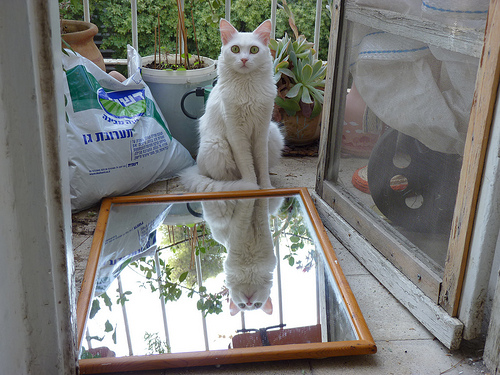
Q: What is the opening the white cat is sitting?
A: A door.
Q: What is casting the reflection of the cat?
A: A mirror.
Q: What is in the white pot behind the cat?
A: A plant.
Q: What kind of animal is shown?
A: Cat.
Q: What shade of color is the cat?
A: White.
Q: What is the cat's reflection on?
A: Mirror.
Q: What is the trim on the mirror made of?
A: Wood.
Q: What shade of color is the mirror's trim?
A: Brown.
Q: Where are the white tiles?
A: On the floor.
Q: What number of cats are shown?
A: 1.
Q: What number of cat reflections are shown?
A: 1.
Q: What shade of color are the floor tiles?
A: White.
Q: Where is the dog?
A: There is no dog.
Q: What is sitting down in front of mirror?
A: A cat.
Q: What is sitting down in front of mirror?
A: White cat.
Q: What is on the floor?
A: A Mirror.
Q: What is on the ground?
A: A Mirror.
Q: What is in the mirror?
A: A reflection.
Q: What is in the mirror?
A: Reflection of white cat.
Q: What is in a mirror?
A: Cats reflection.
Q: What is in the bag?
A: Potting soil.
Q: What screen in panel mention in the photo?
A: Screen panel to the right.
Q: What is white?
A: Cat.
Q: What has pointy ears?
A: The cat.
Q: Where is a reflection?
A: In the mirror.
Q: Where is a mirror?
A: On the floor.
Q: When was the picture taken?
A: Daytime.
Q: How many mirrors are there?
A: One.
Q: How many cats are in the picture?
A: Only one.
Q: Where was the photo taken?
A: On a patio.